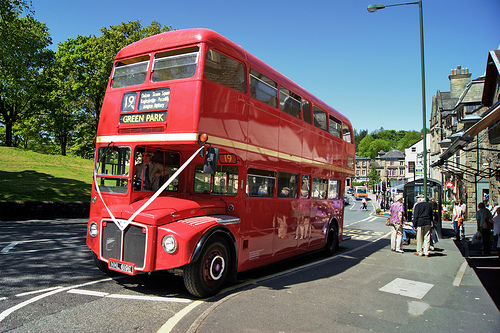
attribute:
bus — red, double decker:
[85, 28, 356, 298]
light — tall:
[367, 0, 427, 201]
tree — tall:
[0, 17, 57, 146]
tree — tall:
[40, 55, 78, 155]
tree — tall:
[51, 36, 119, 121]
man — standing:
[286, 95, 300, 122]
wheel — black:
[183, 235, 229, 296]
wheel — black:
[326, 224, 338, 257]